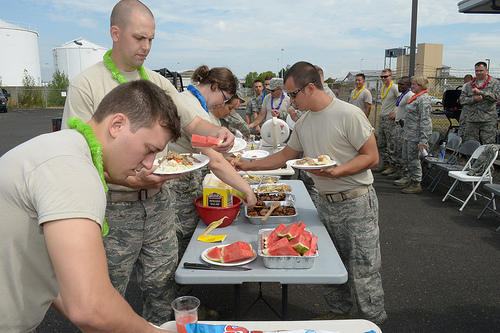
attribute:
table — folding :
[178, 160, 389, 330]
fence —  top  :
[18, 81, 68, 114]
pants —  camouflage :
[103, 180, 388, 331]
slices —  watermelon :
[260, 218, 318, 264]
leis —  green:
[73, 50, 153, 235]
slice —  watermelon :
[190, 130, 230, 154]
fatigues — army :
[111, 189, 392, 328]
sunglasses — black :
[230, 60, 397, 316]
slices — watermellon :
[257, 220, 327, 269]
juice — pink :
[165, 283, 202, 329]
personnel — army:
[6, 1, 490, 286]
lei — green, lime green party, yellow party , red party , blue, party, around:
[469, 74, 496, 95]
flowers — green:
[60, 112, 131, 241]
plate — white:
[202, 242, 250, 270]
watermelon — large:
[261, 222, 319, 259]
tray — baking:
[247, 199, 308, 225]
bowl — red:
[188, 193, 242, 222]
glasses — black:
[279, 84, 313, 101]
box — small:
[200, 185, 231, 205]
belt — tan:
[311, 184, 374, 200]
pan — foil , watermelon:
[247, 187, 295, 203]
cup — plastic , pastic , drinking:
[172, 293, 206, 332]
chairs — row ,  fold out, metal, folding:
[443, 141, 496, 208]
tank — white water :
[48, 34, 102, 80]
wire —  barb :
[365, 68, 498, 78]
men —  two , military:
[392, 76, 427, 199]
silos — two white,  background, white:
[0, 15, 111, 92]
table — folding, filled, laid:
[179, 181, 347, 285]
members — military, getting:
[9, 1, 493, 301]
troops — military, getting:
[14, 0, 491, 298]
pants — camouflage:
[311, 189, 389, 312]